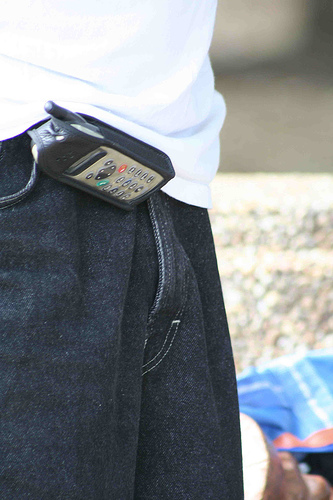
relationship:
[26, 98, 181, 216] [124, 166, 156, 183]
phone has buttons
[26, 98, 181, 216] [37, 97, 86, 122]
phone has antenna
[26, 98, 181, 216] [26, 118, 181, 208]
phone in case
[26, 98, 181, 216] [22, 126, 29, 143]
phone on belt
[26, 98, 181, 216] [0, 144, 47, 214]
cell phone in pocket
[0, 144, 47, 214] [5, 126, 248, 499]
pocket of jeans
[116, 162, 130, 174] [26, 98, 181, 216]
button on phone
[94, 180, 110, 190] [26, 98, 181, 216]
button on phone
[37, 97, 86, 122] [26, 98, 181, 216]
antenna on phone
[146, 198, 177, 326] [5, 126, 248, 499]
fly on jeans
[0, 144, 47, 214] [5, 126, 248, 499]
pocket on jeans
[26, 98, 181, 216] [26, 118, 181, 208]
cellphone in case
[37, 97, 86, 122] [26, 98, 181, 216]
antenna of cellphone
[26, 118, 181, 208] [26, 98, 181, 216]
case on phone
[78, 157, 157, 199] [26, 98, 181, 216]
keypad on cellphone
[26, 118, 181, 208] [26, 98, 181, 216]
case of phone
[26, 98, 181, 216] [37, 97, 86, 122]
phone with antenna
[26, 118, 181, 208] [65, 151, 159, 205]
case has front